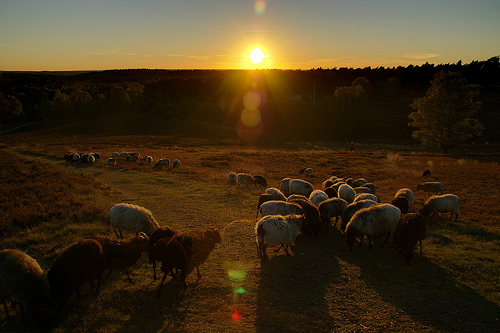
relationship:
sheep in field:
[40, 108, 486, 331] [31, 136, 476, 329]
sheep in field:
[246, 167, 478, 286] [3, 141, 496, 326]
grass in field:
[2, 134, 493, 328] [3, 141, 496, 326]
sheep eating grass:
[246, 167, 478, 286] [2, 134, 493, 328]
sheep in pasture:
[243, 156, 464, 292] [0, 146, 495, 331]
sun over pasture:
[227, 36, 282, 83] [0, 146, 495, 331]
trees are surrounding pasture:
[5, 61, 497, 141] [0, 146, 495, 331]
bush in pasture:
[405, 149, 497, 200] [0, 146, 495, 331]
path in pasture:
[10, 134, 465, 324] [0, 146, 495, 331]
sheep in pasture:
[2, 146, 476, 327] [0, 146, 495, 331]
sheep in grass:
[249, 170, 467, 268] [2, 134, 493, 328]